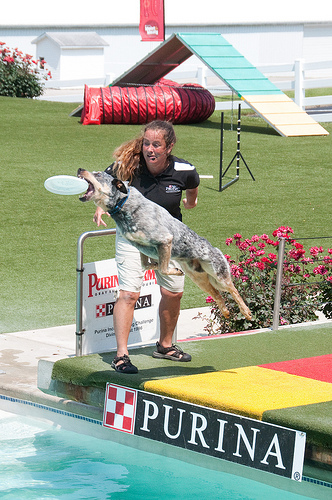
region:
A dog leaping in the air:
[76, 168, 256, 318]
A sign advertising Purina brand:
[100, 381, 303, 481]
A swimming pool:
[0, 385, 330, 496]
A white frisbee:
[43, 175, 87, 194]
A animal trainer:
[98, 122, 200, 374]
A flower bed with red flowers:
[210, 227, 331, 330]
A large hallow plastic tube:
[84, 77, 214, 123]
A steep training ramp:
[70, 32, 328, 135]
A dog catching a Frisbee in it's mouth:
[46, 167, 254, 320]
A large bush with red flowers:
[0, 40, 53, 95]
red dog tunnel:
[77, 76, 227, 133]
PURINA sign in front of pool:
[104, 381, 310, 492]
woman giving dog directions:
[45, 123, 257, 373]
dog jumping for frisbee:
[30, 150, 255, 337]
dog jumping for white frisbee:
[43, 152, 256, 325]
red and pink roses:
[205, 228, 330, 333]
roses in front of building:
[0, 39, 56, 104]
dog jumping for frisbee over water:
[4, 107, 248, 494]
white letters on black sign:
[142, 396, 295, 481]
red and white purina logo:
[102, 386, 140, 436]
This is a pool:
[46, 435, 53, 483]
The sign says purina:
[86, 388, 247, 448]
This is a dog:
[83, 145, 271, 268]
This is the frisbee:
[29, 159, 121, 232]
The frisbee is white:
[42, 153, 95, 239]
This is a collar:
[106, 206, 128, 215]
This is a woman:
[101, 142, 201, 192]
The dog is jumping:
[68, 140, 210, 248]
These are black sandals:
[87, 319, 190, 376]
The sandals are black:
[103, 330, 164, 376]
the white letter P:
[139, 396, 159, 435]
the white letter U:
[159, 400, 186, 446]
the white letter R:
[183, 406, 214, 455]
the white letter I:
[207, 410, 234, 457]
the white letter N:
[229, 414, 263, 468]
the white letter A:
[257, 423, 292, 484]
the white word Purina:
[127, 385, 303, 482]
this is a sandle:
[109, 351, 143, 380]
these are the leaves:
[234, 313, 244, 326]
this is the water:
[55, 454, 102, 484]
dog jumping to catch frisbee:
[40, 163, 253, 328]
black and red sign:
[100, 379, 309, 489]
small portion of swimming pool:
[1, 390, 327, 498]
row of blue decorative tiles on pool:
[1, 392, 331, 499]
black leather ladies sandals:
[111, 341, 195, 378]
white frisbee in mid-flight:
[40, 174, 89, 200]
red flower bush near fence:
[204, 223, 331, 332]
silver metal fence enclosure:
[267, 232, 329, 336]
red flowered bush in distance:
[0, 40, 56, 108]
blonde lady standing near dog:
[89, 114, 213, 380]